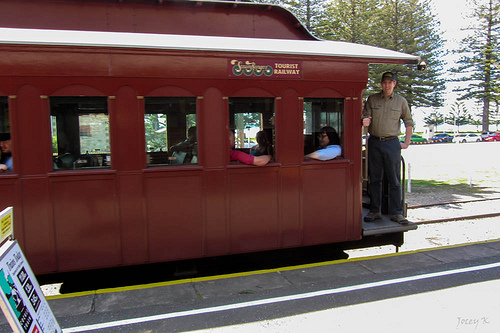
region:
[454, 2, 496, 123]
a big pine tree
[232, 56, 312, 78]
tourist railway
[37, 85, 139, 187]
window in the train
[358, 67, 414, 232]
the man is wearing a hat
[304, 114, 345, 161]
the lady is wearing glasses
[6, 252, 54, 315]
times the train leaves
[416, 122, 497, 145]
parking area for vehicles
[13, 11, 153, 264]
the train is maroon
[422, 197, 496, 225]
train track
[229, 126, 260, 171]
the man has a pink shirt on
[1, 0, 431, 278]
red train on train tracks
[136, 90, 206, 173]
window on side of train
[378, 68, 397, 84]
black baseball cap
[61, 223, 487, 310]
yellow line on train platform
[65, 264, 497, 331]
white line on train platform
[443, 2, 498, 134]
tall pine tree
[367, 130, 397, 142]
brown leather belt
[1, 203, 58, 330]
marketing sign on sidewalk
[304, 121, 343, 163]
person in blue shirt sitting in window of train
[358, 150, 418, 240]
stairs on side of train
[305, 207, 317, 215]
part of a train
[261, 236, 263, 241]
edge of a train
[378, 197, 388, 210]
part of a shoe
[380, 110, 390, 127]
man wearing tan shirt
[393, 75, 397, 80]
man wearing blue hat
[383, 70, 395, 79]
yellow lettering on hat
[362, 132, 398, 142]
man with brown belt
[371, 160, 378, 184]
man wearing blue pants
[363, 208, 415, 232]
man wearing grey shoes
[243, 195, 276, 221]
red paint on train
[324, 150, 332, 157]
woman wearing blue shirt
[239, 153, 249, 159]
woman wearing pink shirt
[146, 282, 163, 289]
yellow line on platform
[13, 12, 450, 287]
this is a train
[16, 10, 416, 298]
the train is maroon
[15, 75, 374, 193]
row of windows on the train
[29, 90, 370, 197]
people inside the train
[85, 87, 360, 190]
people are sitting down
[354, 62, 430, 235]
this is a man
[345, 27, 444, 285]
man is standing on the train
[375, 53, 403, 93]
man wearing a hat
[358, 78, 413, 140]
man wearing a brown shirt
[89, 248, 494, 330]
white lines on the platform